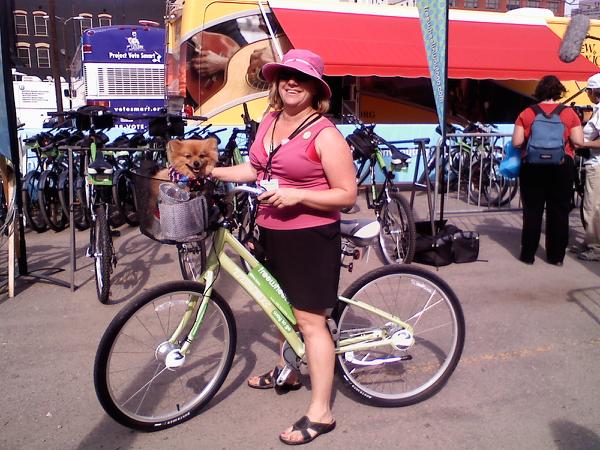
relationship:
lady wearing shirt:
[210, 48, 359, 443] [248, 104, 341, 230]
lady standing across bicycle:
[210, 48, 359, 443] [93, 166, 466, 433]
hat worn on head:
[259, 46, 334, 102] [272, 45, 321, 108]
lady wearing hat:
[210, 48, 359, 443] [259, 46, 334, 102]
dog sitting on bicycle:
[148, 138, 218, 215] [93, 166, 466, 433]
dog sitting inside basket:
[148, 138, 218, 215] [122, 164, 215, 245]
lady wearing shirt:
[513, 74, 584, 267] [513, 98, 581, 157]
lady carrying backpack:
[513, 74, 584, 267] [520, 101, 568, 169]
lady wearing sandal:
[210, 48, 359, 443] [276, 413, 339, 447]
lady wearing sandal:
[210, 48, 359, 443] [248, 367, 302, 391]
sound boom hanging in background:
[556, 9, 582, 64] [2, 2, 579, 239]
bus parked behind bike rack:
[59, 25, 166, 132] [17, 136, 436, 237]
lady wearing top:
[210, 48, 359, 443] [246, 107, 345, 231]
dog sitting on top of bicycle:
[148, 138, 218, 215] [93, 166, 466, 433]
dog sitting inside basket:
[148, 138, 218, 215] [122, 158, 214, 246]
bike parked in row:
[18, 107, 60, 231] [16, 103, 261, 230]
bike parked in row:
[34, 111, 71, 233] [16, 103, 261, 230]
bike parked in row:
[55, 106, 88, 230] [16, 103, 261, 230]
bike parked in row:
[129, 107, 204, 223] [16, 103, 261, 230]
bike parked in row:
[118, 109, 145, 225] [16, 103, 261, 230]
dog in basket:
[111, 117, 229, 238] [114, 151, 233, 261]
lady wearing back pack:
[513, 74, 584, 267] [510, 99, 573, 174]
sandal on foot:
[258, 379, 411, 447] [274, 388, 383, 445]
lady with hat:
[210, 48, 359, 443] [244, 27, 360, 124]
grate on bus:
[79, 52, 225, 125] [45, 20, 166, 134]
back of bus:
[44, 27, 166, 125] [45, 20, 166, 134]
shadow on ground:
[535, 398, 581, 447] [483, 379, 570, 447]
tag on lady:
[235, 169, 309, 221] [228, 22, 390, 415]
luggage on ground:
[386, 204, 495, 289] [470, 271, 580, 386]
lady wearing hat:
[210, 48, 359, 443] [243, 32, 381, 124]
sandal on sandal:
[279, 415, 337, 446] [279, 415, 337, 446]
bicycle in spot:
[72, 183, 533, 413] [48, 283, 571, 447]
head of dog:
[152, 128, 242, 231] [151, 111, 280, 230]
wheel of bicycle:
[332, 244, 504, 425] [92, 227, 571, 404]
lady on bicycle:
[226, 4, 406, 445] [56, 216, 530, 408]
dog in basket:
[148, 138, 218, 215] [109, 189, 223, 242]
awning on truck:
[264, 10, 580, 129] [157, 10, 545, 204]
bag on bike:
[338, 118, 384, 193] [330, 87, 436, 288]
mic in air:
[538, 9, 581, 72] [504, 4, 530, 67]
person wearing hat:
[570, 70, 582, 106] [576, 62, 582, 83]